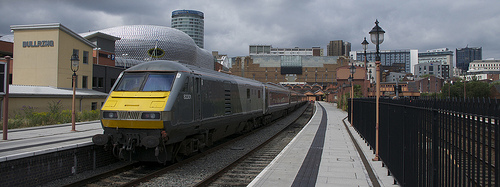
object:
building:
[0, 22, 121, 128]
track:
[90, 100, 313, 170]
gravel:
[152, 157, 228, 182]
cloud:
[0, 0, 498, 48]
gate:
[346, 96, 500, 187]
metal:
[349, 98, 500, 187]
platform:
[1, 127, 93, 159]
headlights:
[100, 109, 122, 120]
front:
[100, 89, 169, 130]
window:
[111, 70, 183, 93]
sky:
[0, 0, 499, 44]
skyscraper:
[168, 9, 205, 48]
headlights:
[137, 111, 162, 121]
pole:
[373, 43, 380, 160]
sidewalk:
[314, 106, 341, 187]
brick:
[327, 114, 357, 178]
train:
[90, 59, 306, 167]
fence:
[344, 94, 499, 187]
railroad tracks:
[72, 99, 310, 181]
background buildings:
[225, 40, 499, 104]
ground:
[245, 113, 395, 184]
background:
[0, 0, 496, 90]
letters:
[21, 40, 53, 48]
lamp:
[368, 19, 385, 45]